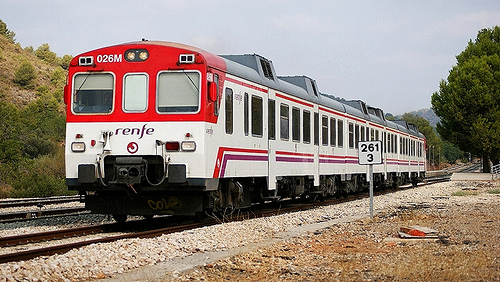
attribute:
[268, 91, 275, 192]
door — white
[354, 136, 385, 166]
sign — white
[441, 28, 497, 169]
tree — large, full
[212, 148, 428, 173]
stripes — red , purple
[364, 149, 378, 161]
3 — number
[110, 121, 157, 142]
word "renfe" — blue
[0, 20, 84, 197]
grassy hill — small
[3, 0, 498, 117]
sky — cloudy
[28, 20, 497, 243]
train — red, white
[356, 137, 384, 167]
sign — black, white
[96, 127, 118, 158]
horn — white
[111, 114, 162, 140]
logo — renfe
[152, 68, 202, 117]
window — square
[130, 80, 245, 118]
window — square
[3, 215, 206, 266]
track —  train's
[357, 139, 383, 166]
sign — white, black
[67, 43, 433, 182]
train — red, white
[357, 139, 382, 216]
sign — white, black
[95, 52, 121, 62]
print — white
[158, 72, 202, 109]
blinds — white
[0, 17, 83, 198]
hill — green